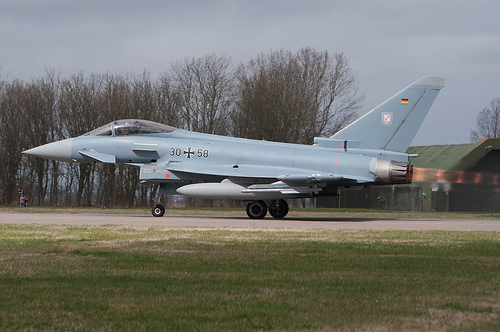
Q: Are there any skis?
A: No, there are no skis.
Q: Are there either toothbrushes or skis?
A: No, there are no skis or toothbrushes.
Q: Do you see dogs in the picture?
A: No, there are no dogs.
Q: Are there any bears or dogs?
A: No, there are no dogs or bears.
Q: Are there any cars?
A: No, there are no cars.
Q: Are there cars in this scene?
A: No, there are no cars.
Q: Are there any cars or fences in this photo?
A: No, there are no cars or fences.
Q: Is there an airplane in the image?
A: Yes, there is an airplane.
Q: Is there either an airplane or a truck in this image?
A: Yes, there is an airplane.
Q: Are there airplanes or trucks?
A: Yes, there is an airplane.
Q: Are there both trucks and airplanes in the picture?
A: No, there is an airplane but no trucks.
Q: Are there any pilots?
A: No, there are no pilots.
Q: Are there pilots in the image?
A: No, there are no pilots.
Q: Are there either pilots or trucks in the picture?
A: No, there are no pilots or trucks.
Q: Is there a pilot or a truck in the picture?
A: No, there are no pilots or trucks.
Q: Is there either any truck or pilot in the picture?
A: No, there are no pilots or trucks.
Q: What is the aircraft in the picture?
A: The aircraft is an airplane.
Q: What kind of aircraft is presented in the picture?
A: The aircraft is an airplane.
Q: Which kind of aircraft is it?
A: The aircraft is an airplane.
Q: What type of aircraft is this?
A: That is an airplane.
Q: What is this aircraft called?
A: That is an airplane.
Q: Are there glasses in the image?
A: No, there are no glasses.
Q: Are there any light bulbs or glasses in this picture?
A: No, there are no glasses or light bulbs.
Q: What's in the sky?
A: The clouds are in the sky.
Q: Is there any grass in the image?
A: Yes, there is grass.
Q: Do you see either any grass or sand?
A: Yes, there is grass.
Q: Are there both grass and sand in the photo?
A: No, there is grass but no sand.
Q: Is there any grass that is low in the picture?
A: Yes, there is low grass.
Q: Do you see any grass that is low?
A: Yes, there is grass that is low.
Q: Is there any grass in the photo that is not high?
A: Yes, there is low grass.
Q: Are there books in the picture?
A: No, there are no books.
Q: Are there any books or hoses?
A: No, there are no books or hoses.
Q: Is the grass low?
A: Yes, the grass is low.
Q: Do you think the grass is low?
A: Yes, the grass is low.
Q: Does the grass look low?
A: Yes, the grass is low.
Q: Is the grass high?
A: No, the grass is low.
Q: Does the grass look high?
A: No, the grass is low.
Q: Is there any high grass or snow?
A: No, there is grass but it is low.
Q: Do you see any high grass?
A: No, there is grass but it is low.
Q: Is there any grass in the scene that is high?
A: No, there is grass but it is low.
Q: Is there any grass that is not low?
A: No, there is grass but it is low.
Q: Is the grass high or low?
A: The grass is low.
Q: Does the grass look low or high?
A: The grass is low.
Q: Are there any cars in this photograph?
A: No, there are no cars.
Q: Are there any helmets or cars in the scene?
A: No, there are no cars or helmets.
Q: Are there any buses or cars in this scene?
A: No, there are no cars or buses.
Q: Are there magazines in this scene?
A: No, there are no magazines.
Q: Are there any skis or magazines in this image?
A: No, there are no magazines or skis.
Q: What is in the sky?
A: The clouds are in the sky.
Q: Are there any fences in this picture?
A: No, there are no fences.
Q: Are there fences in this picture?
A: No, there are no fences.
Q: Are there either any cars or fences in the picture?
A: No, there are no fences or cars.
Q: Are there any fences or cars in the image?
A: No, there are no fences or cars.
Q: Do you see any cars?
A: No, there are no cars.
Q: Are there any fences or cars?
A: No, there are no cars or fences.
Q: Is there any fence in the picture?
A: No, there are no fences.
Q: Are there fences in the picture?
A: No, there are no fences.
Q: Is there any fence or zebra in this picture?
A: No, there are no fences or zebras.